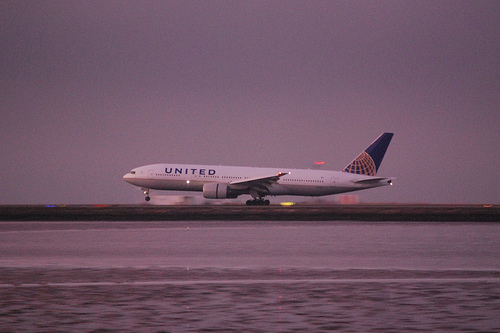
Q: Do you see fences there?
A: No, there are no fences.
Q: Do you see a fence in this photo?
A: No, there are no fences.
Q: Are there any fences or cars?
A: No, there are no fences or cars.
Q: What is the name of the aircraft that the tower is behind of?
A: The aircraft is an airplane.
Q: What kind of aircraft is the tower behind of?
A: The tower is behind the airplane.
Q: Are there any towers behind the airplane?
A: Yes, there is a tower behind the airplane.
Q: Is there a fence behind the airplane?
A: No, there is a tower behind the airplane.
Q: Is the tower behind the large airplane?
A: Yes, the tower is behind the plane.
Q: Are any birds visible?
A: No, there are no birds.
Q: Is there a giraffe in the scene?
A: No, there are no giraffes.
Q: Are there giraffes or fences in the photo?
A: No, there are no giraffes or fences.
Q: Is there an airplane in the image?
A: Yes, there is an airplane.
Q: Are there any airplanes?
A: Yes, there is an airplane.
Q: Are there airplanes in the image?
A: Yes, there is an airplane.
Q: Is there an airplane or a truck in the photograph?
A: Yes, there is an airplane.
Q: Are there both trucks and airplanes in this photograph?
A: No, there is an airplane but no trucks.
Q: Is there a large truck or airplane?
A: Yes, there is a large airplane.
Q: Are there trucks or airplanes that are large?
A: Yes, the airplane is large.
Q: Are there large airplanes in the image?
A: Yes, there is a large airplane.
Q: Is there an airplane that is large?
A: Yes, there is an airplane that is large.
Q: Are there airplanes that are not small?
A: Yes, there is a large airplane.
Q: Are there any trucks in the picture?
A: No, there are no trucks.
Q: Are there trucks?
A: No, there are no trucks.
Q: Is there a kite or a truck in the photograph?
A: No, there are no trucks or kites.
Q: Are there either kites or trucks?
A: No, there are no trucks or kites.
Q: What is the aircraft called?
A: The aircraft is an airplane.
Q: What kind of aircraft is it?
A: The aircraft is an airplane.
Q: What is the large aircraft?
A: The aircraft is an airplane.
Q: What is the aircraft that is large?
A: The aircraft is an airplane.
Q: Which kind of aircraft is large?
A: The aircraft is an airplane.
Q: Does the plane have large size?
A: Yes, the plane is large.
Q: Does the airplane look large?
A: Yes, the airplane is large.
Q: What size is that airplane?
A: The airplane is large.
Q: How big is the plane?
A: The plane is large.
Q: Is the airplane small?
A: No, the airplane is large.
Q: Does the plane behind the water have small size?
A: No, the plane is large.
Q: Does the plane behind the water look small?
A: No, the plane is large.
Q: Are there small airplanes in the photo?
A: No, there is an airplane but it is large.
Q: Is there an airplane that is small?
A: No, there is an airplane but it is large.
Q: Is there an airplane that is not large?
A: No, there is an airplane but it is large.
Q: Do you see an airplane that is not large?
A: No, there is an airplane but it is large.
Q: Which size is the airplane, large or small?
A: The airplane is large.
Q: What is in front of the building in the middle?
A: The plane is in front of the tower.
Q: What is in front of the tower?
A: The plane is in front of the tower.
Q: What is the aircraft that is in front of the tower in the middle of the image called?
A: The aircraft is an airplane.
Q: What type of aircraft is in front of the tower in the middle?
A: The aircraft is an airplane.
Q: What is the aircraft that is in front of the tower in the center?
A: The aircraft is an airplane.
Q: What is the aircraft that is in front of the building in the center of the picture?
A: The aircraft is an airplane.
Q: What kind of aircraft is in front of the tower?
A: The aircraft is an airplane.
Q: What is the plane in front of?
A: The plane is in front of the tower.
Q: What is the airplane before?
A: The plane is in front of the tower.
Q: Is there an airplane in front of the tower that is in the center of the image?
A: Yes, there is an airplane in front of the tower.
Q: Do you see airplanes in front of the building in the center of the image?
A: Yes, there is an airplane in front of the tower.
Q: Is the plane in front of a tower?
A: Yes, the plane is in front of a tower.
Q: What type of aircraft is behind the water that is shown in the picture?
A: The aircraft is an airplane.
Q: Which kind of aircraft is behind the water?
A: The aircraft is an airplane.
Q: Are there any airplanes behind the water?
A: Yes, there is an airplane behind the water.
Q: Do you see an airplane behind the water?
A: Yes, there is an airplane behind the water.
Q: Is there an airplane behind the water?
A: Yes, there is an airplane behind the water.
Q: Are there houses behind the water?
A: No, there is an airplane behind the water.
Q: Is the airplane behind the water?
A: Yes, the airplane is behind the water.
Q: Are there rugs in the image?
A: No, there are no rugs.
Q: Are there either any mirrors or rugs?
A: No, there are no rugs or mirrors.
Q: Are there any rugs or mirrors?
A: No, there are no rugs or mirrors.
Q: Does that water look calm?
A: Yes, the water is calm.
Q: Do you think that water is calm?
A: Yes, the water is calm.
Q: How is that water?
A: The water is calm.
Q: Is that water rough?
A: No, the water is calm.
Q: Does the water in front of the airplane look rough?
A: No, the water is calm.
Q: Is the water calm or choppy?
A: The water is calm.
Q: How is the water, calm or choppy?
A: The water is calm.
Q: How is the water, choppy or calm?
A: The water is calm.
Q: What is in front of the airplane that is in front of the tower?
A: The water is in front of the plane.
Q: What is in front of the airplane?
A: The water is in front of the plane.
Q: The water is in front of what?
A: The water is in front of the plane.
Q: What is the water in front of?
A: The water is in front of the plane.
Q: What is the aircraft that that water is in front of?
A: The aircraft is an airplane.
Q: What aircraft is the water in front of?
A: The water is in front of the airplane.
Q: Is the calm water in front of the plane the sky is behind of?
A: Yes, the water is in front of the airplane.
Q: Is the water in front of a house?
A: No, the water is in front of the airplane.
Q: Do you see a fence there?
A: No, there are no fences.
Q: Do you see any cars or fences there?
A: No, there are no fences or cars.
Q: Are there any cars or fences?
A: No, there are no fences or cars.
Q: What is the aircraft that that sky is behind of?
A: The aircraft is an airplane.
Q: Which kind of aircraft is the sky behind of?
A: The sky is behind the plane.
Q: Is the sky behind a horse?
A: No, the sky is behind the airplane.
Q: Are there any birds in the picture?
A: No, there are no birds.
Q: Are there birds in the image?
A: No, there are no birds.